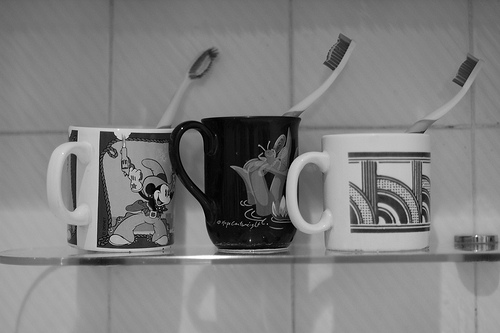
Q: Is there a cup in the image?
A: Yes, there is a cup.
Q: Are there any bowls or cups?
A: Yes, there is a cup.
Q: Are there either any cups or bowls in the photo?
A: Yes, there is a cup.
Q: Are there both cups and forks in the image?
A: No, there is a cup but no forks.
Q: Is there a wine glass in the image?
A: No, there are no wine glasses.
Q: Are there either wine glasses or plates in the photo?
A: No, there are no wine glasses or plates.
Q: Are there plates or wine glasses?
A: No, there are no wine glasses or plates.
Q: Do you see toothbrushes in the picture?
A: Yes, there is a toothbrush.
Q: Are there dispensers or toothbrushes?
A: Yes, there is a toothbrush.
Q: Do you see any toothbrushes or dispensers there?
A: Yes, there is a toothbrush.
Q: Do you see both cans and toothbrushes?
A: No, there is a toothbrush but no cans.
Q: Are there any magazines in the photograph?
A: No, there are no magazines.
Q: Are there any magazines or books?
A: No, there are no magazines or books.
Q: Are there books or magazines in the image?
A: No, there are no magazines or books.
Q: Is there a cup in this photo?
A: Yes, there is a cup.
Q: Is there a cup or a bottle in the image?
A: Yes, there is a cup.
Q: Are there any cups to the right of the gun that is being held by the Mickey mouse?
A: Yes, there is a cup to the right of the gun.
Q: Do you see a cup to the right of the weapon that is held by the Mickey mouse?
A: Yes, there is a cup to the right of the gun.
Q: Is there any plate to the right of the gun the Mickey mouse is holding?
A: No, there is a cup to the right of the gun.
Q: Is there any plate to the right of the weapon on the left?
A: No, there is a cup to the right of the gun.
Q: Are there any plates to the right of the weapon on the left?
A: No, there is a cup to the right of the gun.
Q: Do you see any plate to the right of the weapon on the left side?
A: No, there is a cup to the right of the gun.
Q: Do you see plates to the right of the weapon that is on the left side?
A: No, there is a cup to the right of the gun.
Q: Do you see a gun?
A: Yes, there is a gun.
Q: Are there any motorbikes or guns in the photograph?
A: Yes, there is a gun.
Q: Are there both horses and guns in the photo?
A: No, there is a gun but no horses.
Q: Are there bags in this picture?
A: No, there are no bags.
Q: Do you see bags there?
A: No, there are no bags.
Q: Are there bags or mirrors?
A: No, there are no bags or mirrors.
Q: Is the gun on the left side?
A: Yes, the gun is on the left of the image.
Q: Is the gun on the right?
A: No, the gun is on the left of the image.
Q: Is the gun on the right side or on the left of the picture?
A: The gun is on the left of the image.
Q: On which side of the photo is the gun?
A: The gun is on the left of the image.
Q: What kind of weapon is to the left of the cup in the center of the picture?
A: The weapon is a gun.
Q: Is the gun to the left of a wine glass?
A: No, the gun is to the left of the cup.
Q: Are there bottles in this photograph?
A: No, there are no bottles.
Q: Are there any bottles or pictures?
A: No, there are no bottles or pictures.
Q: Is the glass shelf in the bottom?
A: Yes, the shelf is in the bottom of the image.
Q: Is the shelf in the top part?
A: No, the shelf is in the bottom of the image.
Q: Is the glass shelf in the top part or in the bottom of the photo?
A: The shelf is in the bottom of the image.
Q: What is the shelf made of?
A: The shelf is made of glass.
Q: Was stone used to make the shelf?
A: No, the shelf is made of glass.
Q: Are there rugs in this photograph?
A: No, there are no rugs.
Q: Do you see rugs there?
A: No, there are no rugs.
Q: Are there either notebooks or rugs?
A: No, there are no rugs or notebooks.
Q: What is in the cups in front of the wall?
A: The toothbrushes are in the cups.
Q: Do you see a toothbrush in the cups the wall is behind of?
A: Yes, there are toothbrushes in the cups.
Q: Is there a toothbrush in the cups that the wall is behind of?
A: Yes, there are toothbrushes in the cups.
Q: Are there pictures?
A: No, there are no pictures.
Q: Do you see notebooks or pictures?
A: No, there are no pictures or notebooks.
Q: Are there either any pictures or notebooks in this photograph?
A: No, there are no pictures or notebooks.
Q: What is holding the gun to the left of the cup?
A: The Mickey mouse is holding the gun.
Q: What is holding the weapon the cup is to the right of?
A: The Mickey mouse is holding the gun.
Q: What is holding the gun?
A: The Mickey mouse is holding the gun.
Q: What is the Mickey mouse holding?
A: The Mickey mouse is holding the gun.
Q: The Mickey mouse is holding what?
A: The Mickey mouse is holding the gun.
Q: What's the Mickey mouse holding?
A: The Mickey mouse is holding the gun.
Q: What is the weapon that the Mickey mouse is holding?
A: The weapon is a gun.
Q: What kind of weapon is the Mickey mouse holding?
A: The Mickey mouse is holding the gun.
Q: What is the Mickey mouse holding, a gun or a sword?
A: The Mickey mouse is holding a gun.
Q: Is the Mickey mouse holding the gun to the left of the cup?
A: Yes, the Mickey mouse is holding the gun.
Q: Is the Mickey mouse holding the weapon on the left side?
A: Yes, the Mickey mouse is holding the gun.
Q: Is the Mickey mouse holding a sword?
A: No, the Mickey mouse is holding the gun.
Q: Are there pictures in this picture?
A: No, there are no pictures.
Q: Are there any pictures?
A: No, there are no pictures.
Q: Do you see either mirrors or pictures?
A: No, there are no pictures or mirrors.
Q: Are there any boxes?
A: No, there are no boxes.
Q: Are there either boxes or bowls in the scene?
A: No, there are no boxes or bowls.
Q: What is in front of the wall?
A: The cups are in front of the wall.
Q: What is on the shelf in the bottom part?
A: The cups are on the shelf.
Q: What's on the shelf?
A: The cups are on the shelf.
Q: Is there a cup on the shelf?
A: Yes, there are cups on the shelf.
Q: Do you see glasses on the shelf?
A: No, there are cups on the shelf.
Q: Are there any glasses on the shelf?
A: No, there are cups on the shelf.